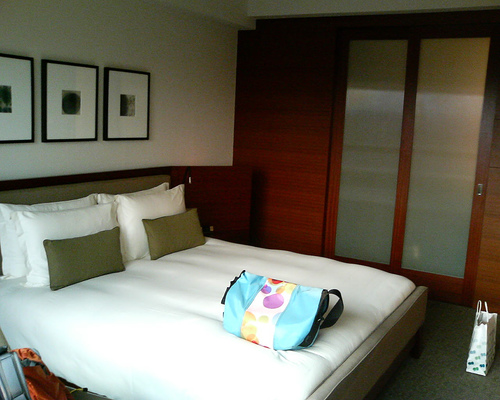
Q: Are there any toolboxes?
A: No, there are no toolboxes.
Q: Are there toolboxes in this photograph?
A: No, there are no toolboxes.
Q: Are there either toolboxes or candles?
A: No, there are no toolboxes or candles.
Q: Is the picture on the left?
A: Yes, the picture is on the left of the image.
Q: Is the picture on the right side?
A: No, the picture is on the left of the image.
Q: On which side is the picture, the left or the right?
A: The picture is on the left of the image.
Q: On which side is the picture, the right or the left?
A: The picture is on the left of the image.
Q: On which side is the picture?
A: The picture is on the left of the image.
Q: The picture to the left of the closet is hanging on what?
A: The picture is hanging on the wall.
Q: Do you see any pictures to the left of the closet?
A: Yes, there is a picture to the left of the closet.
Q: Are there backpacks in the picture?
A: Yes, there is a backpack.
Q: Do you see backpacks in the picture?
A: Yes, there is a backpack.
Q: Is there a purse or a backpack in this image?
A: Yes, there is a backpack.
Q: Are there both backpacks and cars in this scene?
A: No, there is a backpack but no cars.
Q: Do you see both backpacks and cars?
A: No, there is a backpack but no cars.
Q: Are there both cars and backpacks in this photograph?
A: No, there is a backpack but no cars.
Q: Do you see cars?
A: No, there are no cars.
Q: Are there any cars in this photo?
A: No, there are no cars.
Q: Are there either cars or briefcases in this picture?
A: No, there are no cars or briefcases.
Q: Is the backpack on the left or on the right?
A: The backpack is on the left of the image.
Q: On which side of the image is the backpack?
A: The backpack is on the left of the image.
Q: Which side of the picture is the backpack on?
A: The backpack is on the left of the image.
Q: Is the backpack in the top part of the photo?
A: No, the backpack is in the bottom of the image.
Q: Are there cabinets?
A: Yes, there is a cabinet.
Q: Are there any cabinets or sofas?
A: Yes, there is a cabinet.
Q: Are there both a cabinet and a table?
A: No, there is a cabinet but no tables.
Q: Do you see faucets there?
A: No, there are no faucets.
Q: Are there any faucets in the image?
A: No, there are no faucets.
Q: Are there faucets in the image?
A: No, there are no faucets.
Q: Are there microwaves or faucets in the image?
A: No, there are no faucets or microwaves.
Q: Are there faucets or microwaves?
A: No, there are no faucets or microwaves.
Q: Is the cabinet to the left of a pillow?
A: No, the cabinet is to the right of a pillow.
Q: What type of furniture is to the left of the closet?
A: The piece of furniture is a cabinet.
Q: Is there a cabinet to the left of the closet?
A: Yes, there is a cabinet to the left of the closet.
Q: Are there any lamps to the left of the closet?
A: No, there is a cabinet to the left of the closet.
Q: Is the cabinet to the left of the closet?
A: Yes, the cabinet is to the left of the closet.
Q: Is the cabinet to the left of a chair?
A: No, the cabinet is to the left of the closet.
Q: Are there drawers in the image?
A: No, there are no drawers.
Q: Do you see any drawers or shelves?
A: No, there are no drawers or shelves.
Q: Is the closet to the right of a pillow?
A: Yes, the closet is to the right of a pillow.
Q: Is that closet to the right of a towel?
A: No, the closet is to the right of a pillow.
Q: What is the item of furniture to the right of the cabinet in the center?
A: The piece of furniture is a closet.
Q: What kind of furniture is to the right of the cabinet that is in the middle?
A: The piece of furniture is a closet.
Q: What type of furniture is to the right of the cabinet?
A: The piece of furniture is a closet.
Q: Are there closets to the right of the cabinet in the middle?
A: Yes, there is a closet to the right of the cabinet.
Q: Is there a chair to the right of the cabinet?
A: No, there is a closet to the right of the cabinet.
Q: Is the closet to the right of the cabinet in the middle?
A: Yes, the closet is to the right of the cabinet.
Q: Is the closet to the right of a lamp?
A: No, the closet is to the right of the cabinet.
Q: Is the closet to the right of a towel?
A: No, the closet is to the right of a pillow.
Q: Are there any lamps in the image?
A: No, there are no lamps.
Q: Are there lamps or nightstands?
A: No, there are no lamps or nightstands.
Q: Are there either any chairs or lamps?
A: No, there are no chairs or lamps.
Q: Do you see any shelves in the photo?
A: No, there are no shelves.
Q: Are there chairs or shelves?
A: No, there are no shelves or chairs.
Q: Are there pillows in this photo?
A: Yes, there is a pillow.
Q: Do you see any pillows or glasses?
A: Yes, there is a pillow.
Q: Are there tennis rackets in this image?
A: No, there are no tennis rackets.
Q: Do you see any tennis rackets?
A: No, there are no tennis rackets.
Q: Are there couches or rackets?
A: No, there are no rackets or couches.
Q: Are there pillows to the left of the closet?
A: Yes, there is a pillow to the left of the closet.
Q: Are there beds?
A: Yes, there is a bed.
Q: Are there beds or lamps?
A: Yes, there is a bed.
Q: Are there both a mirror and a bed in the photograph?
A: No, there is a bed but no mirrors.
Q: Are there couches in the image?
A: No, there are no couches.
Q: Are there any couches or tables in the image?
A: No, there are no couches or tables.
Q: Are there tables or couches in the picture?
A: No, there are no couches or tables.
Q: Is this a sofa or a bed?
A: This is a bed.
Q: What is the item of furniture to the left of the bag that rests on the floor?
A: The piece of furniture is a bed.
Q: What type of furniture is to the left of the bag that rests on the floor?
A: The piece of furniture is a bed.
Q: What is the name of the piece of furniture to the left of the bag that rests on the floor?
A: The piece of furniture is a bed.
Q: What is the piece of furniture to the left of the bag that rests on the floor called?
A: The piece of furniture is a bed.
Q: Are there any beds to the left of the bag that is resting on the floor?
A: Yes, there is a bed to the left of the bag.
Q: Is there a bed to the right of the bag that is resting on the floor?
A: No, the bed is to the left of the bag.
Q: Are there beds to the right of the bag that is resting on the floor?
A: No, the bed is to the left of the bag.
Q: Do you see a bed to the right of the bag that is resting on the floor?
A: No, the bed is to the left of the bag.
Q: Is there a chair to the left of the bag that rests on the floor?
A: No, there is a bed to the left of the bag.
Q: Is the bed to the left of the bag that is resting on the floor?
A: Yes, the bed is to the left of the bag.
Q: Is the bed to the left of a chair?
A: No, the bed is to the left of the bag.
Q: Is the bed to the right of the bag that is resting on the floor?
A: No, the bed is to the left of the bag.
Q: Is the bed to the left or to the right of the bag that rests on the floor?
A: The bed is to the left of the bag.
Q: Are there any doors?
A: Yes, there is a door.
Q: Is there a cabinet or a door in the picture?
A: Yes, there is a door.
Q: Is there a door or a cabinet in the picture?
A: Yes, there is a door.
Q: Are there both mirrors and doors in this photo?
A: No, there is a door but no mirrors.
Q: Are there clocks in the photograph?
A: No, there are no clocks.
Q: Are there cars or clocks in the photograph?
A: No, there are no clocks or cars.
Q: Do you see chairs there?
A: No, there are no chairs.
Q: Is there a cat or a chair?
A: No, there are no chairs or cats.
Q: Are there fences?
A: No, there are no fences.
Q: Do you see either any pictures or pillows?
A: Yes, there is a pillow.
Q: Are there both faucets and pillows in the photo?
A: No, there is a pillow but no faucets.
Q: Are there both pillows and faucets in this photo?
A: No, there is a pillow but no faucets.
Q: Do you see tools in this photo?
A: No, there are no tools.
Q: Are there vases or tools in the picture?
A: No, there are no tools or vases.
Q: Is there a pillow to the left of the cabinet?
A: Yes, there is a pillow to the left of the cabinet.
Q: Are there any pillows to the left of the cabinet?
A: Yes, there is a pillow to the left of the cabinet.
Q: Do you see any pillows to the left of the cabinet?
A: Yes, there is a pillow to the left of the cabinet.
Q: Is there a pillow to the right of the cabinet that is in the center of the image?
A: No, the pillow is to the left of the cabinet.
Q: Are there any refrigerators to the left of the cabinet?
A: No, there is a pillow to the left of the cabinet.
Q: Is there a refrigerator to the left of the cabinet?
A: No, there is a pillow to the left of the cabinet.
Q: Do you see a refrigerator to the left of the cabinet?
A: No, there is a pillow to the left of the cabinet.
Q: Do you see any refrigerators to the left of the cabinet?
A: No, there is a pillow to the left of the cabinet.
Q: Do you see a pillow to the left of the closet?
A: Yes, there is a pillow to the left of the closet.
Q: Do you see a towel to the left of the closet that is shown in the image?
A: No, there is a pillow to the left of the closet.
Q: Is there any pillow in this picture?
A: Yes, there is a pillow.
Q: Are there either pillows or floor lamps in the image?
A: Yes, there is a pillow.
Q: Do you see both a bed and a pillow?
A: Yes, there are both a pillow and a bed.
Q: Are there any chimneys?
A: No, there are no chimneys.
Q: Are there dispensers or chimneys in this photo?
A: No, there are no chimneys or dispensers.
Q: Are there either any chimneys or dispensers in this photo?
A: No, there are no chimneys or dispensers.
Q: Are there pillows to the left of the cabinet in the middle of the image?
A: Yes, there is a pillow to the left of the cabinet.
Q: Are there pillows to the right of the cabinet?
A: No, the pillow is to the left of the cabinet.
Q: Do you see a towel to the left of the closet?
A: No, there is a pillow to the left of the closet.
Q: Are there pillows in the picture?
A: Yes, there is a pillow.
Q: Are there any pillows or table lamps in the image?
A: Yes, there is a pillow.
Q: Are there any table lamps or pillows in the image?
A: Yes, there is a pillow.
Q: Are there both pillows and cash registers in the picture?
A: No, there is a pillow but no cash registers.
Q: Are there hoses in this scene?
A: No, there are no hoses.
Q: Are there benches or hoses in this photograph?
A: No, there are no hoses or benches.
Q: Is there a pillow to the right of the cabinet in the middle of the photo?
A: No, the pillow is to the left of the cabinet.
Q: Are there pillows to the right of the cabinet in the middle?
A: No, the pillow is to the left of the cabinet.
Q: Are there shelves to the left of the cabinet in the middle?
A: No, there is a pillow to the left of the cabinet.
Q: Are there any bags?
A: Yes, there is a bag.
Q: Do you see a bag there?
A: Yes, there is a bag.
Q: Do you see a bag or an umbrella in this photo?
A: Yes, there is a bag.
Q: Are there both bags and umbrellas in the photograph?
A: No, there is a bag but no umbrellas.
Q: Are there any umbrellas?
A: No, there are no umbrellas.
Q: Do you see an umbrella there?
A: No, there are no umbrellas.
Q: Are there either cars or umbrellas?
A: No, there are no umbrellas or cars.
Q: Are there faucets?
A: No, there are no faucets.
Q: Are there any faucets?
A: No, there are no faucets.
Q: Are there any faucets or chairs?
A: No, there are no faucets or chairs.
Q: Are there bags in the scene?
A: Yes, there is a bag.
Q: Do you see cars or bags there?
A: Yes, there is a bag.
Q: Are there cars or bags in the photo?
A: Yes, there is a bag.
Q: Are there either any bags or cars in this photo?
A: Yes, there is a bag.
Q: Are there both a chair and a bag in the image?
A: No, there is a bag but no chairs.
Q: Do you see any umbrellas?
A: No, there are no umbrellas.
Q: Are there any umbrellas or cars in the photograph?
A: No, there are no umbrellas or cars.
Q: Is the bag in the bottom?
A: Yes, the bag is in the bottom of the image.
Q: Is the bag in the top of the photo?
A: No, the bag is in the bottom of the image.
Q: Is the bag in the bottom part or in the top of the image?
A: The bag is in the bottom of the image.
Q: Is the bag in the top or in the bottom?
A: The bag is in the bottom of the image.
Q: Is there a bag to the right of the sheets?
A: Yes, there is a bag to the right of the sheets.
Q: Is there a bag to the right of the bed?
A: Yes, there is a bag to the right of the bed.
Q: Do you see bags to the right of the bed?
A: Yes, there is a bag to the right of the bed.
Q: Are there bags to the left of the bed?
A: No, the bag is to the right of the bed.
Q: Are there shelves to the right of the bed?
A: No, there is a bag to the right of the bed.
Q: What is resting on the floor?
A: The bag is resting on the floor.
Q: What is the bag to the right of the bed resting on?
A: The bag is resting on the floor.